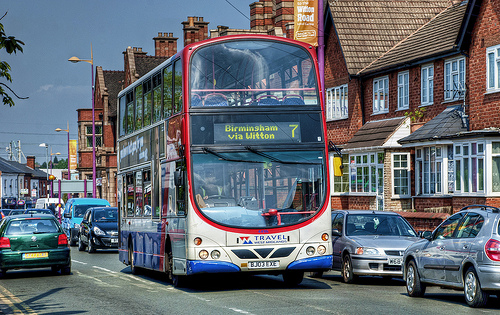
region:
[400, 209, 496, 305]
Silver car parked near curb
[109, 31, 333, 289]
Bus in middle of road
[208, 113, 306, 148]
Digital sign on bus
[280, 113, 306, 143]
Green number on bus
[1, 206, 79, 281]
Green car on road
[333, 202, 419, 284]
Silver car near curb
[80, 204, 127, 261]
Black car behind bus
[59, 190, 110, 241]
Blue van on street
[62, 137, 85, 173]
Sign hanging on pole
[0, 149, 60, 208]
Building in the background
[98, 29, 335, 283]
a double-decker bus on the street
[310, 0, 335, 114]
a lightpole by the bus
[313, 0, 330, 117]
the pole is purple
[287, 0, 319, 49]
an orange sign on the pole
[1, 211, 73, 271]
a green car on the road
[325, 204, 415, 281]
a silver car on the road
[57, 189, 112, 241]
a blue van on the road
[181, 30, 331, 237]
the bus front has a border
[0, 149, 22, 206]
a building down the street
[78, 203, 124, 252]
a blue car behind the bus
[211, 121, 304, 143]
Yellow sign on front of bus.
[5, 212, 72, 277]
Small green car driving on road.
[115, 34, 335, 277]
Red, white, and blue bus.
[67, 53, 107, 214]
Tall light pole on side of street.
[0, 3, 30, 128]
Tree branches hanging over street.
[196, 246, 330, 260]
Small round headlights on front of bus.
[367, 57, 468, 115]
Windows with white frames.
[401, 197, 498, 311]
Silver road parked on side of road.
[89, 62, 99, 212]
Tall purple light pole.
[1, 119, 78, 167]
Power lines above the road.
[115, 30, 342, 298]
double decker bus in street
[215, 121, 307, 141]
the destinatio of the bus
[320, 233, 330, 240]
left headlight on the bus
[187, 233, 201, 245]
right headlight on bus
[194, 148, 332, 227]
bottom windshield on the bus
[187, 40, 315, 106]
top windshield on the bus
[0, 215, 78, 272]
small green car on the road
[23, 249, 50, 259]
license plate on green car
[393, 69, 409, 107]
window on the building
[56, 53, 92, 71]
street light on the pole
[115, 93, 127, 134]
glass window on bus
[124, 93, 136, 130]
glass window on bus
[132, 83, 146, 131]
glass window on bus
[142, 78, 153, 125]
glass window on bus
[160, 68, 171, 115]
glass window on bus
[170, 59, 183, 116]
glass window on bus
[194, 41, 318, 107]
glass window on bus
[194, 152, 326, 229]
glass window on bus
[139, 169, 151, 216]
glass window on bus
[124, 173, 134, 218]
glass window on bus